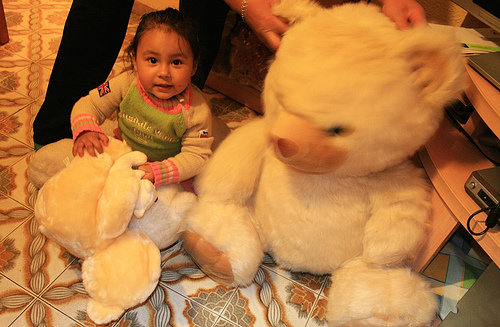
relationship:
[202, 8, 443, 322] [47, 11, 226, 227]
animal next to child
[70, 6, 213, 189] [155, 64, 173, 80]
child has nose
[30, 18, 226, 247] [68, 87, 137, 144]
child has arm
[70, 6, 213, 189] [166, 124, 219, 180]
child has arm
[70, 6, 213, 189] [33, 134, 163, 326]
child holding bear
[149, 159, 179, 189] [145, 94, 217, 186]
stripes on sleeve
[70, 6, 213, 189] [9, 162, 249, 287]
child sitting on floor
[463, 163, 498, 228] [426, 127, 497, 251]
electronic on shelf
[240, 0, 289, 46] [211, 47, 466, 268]
hand on side of bear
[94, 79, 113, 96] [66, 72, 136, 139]
design on sleeve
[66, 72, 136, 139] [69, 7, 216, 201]
sleeve of child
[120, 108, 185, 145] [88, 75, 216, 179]
writing on front of shirt